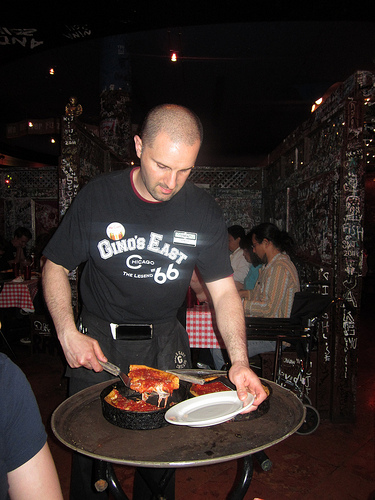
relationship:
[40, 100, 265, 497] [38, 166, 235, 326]
man in shirt